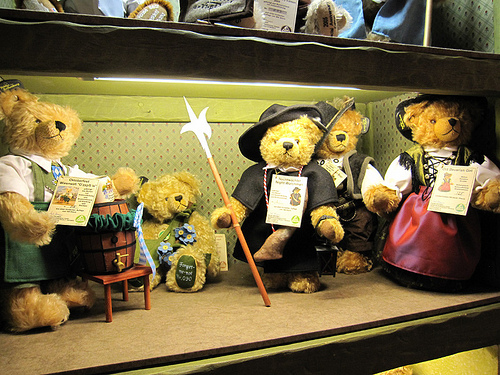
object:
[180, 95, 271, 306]
pole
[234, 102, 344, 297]
bear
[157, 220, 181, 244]
tie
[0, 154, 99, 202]
shirt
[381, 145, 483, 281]
dress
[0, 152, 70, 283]
jumper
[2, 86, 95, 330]
bear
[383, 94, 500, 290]
bear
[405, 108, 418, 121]
ground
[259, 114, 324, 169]
head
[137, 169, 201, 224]
head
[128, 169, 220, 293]
tedbear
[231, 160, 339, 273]
jacket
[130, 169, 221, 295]
bear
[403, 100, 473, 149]
head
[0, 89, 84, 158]
head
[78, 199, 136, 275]
barrel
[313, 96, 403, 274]
teddy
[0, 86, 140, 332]
teddy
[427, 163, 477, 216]
paper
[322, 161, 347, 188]
paper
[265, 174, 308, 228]
paper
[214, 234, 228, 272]
paper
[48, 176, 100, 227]
paper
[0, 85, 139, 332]
bear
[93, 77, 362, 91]
light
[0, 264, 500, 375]
table